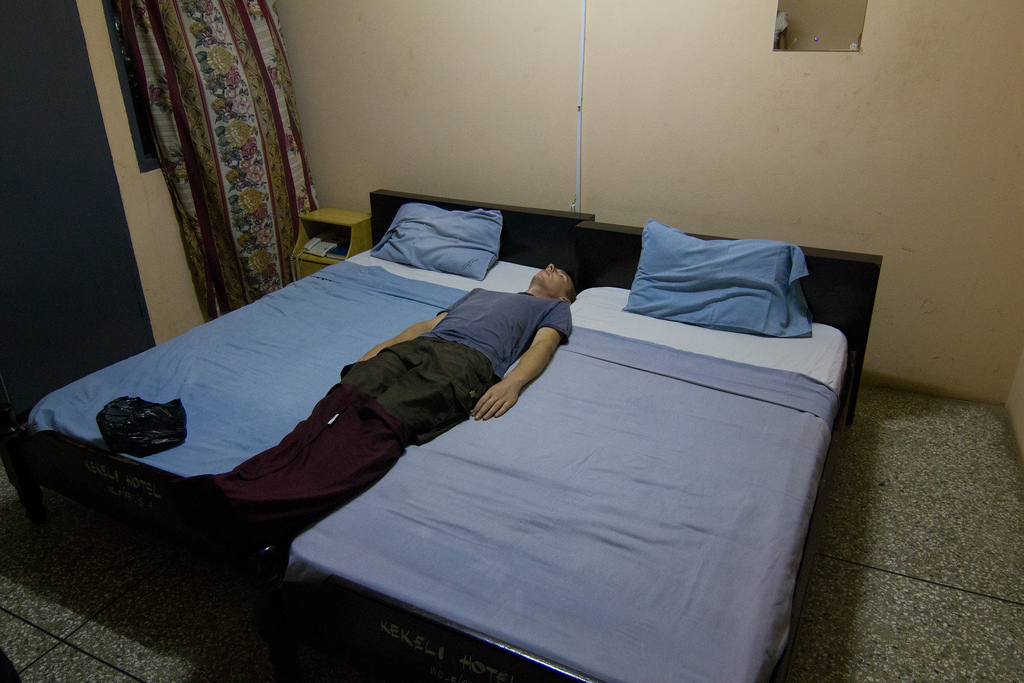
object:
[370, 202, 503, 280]
pillow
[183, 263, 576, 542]
man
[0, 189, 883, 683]
bed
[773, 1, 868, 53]
marrow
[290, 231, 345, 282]
phone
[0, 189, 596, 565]
bed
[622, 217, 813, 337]
pillow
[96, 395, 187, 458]
bag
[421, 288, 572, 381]
shirt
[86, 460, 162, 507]
writing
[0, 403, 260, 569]
headboard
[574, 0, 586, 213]
white cord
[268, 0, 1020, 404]
wall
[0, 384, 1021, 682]
floor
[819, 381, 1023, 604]
tile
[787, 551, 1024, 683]
tile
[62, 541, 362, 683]
tile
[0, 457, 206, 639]
tile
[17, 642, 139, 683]
tile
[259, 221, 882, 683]
bed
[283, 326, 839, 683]
blue bedding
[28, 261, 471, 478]
blue bedding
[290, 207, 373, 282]
night stand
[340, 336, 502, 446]
khaki's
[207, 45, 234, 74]
flower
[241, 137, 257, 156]
flower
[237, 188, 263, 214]
flower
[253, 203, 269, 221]
flower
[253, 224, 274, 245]
flower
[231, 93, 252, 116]
flower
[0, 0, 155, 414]
door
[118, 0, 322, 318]
curtain